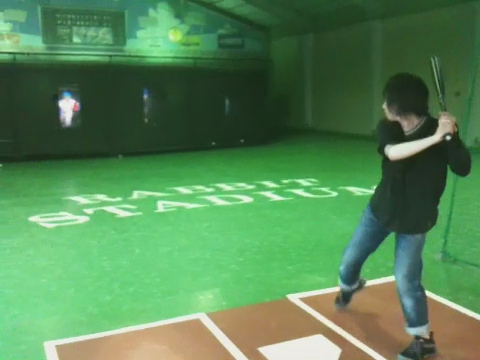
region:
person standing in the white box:
[287, 44, 472, 355]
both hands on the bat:
[425, 59, 460, 155]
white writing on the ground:
[26, 144, 380, 248]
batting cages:
[0, 0, 475, 353]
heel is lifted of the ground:
[325, 271, 362, 309]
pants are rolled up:
[327, 271, 432, 336]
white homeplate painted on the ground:
[252, 327, 342, 355]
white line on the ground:
[40, 302, 201, 347]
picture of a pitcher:
[53, 83, 79, 121]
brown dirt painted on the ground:
[39, 276, 479, 358]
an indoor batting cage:
[294, 14, 475, 358]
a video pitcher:
[39, 61, 102, 141]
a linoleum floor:
[2, 140, 453, 359]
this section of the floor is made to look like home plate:
[54, 253, 458, 358]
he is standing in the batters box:
[292, 273, 478, 358]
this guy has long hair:
[316, 24, 478, 358]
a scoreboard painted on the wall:
[34, 5, 142, 55]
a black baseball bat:
[424, 48, 457, 147]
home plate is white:
[244, 323, 340, 357]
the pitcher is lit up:
[52, 79, 92, 137]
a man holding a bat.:
[336, 44, 464, 359]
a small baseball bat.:
[418, 42, 461, 186]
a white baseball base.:
[252, 318, 345, 358]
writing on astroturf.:
[12, 176, 389, 230]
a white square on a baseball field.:
[41, 299, 256, 359]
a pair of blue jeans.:
[325, 194, 444, 337]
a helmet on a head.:
[377, 57, 436, 136]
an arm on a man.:
[380, 107, 458, 186]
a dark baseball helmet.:
[385, 59, 450, 131]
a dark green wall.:
[111, 40, 258, 140]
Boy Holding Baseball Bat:
[324, 49, 471, 356]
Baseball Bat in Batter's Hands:
[422, 49, 457, 138]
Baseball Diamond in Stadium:
[252, 329, 348, 353]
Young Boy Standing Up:
[330, 68, 468, 356]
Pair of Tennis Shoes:
[324, 272, 441, 354]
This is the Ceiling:
[185, 0, 475, 30]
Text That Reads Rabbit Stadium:
[15, 170, 390, 229]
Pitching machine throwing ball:
[52, 85, 77, 123]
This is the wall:
[266, 3, 474, 138]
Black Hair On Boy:
[374, 67, 433, 122]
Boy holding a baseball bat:
[336, 53, 469, 354]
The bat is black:
[428, 55, 452, 142]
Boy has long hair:
[381, 73, 429, 116]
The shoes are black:
[336, 274, 436, 359]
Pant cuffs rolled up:
[338, 277, 432, 330]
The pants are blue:
[337, 204, 427, 328]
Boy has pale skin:
[381, 92, 455, 159]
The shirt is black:
[370, 116, 468, 231]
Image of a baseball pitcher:
[53, 82, 83, 129]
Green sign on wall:
[39, 6, 125, 48]